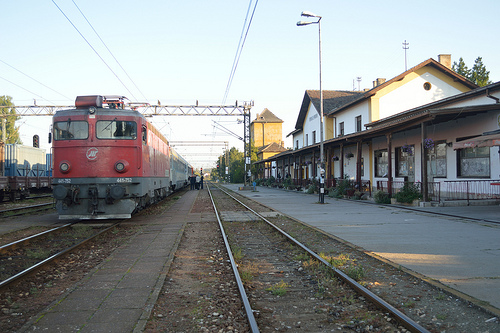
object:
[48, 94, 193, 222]
train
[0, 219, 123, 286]
tracks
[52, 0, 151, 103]
power lines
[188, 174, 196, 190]
people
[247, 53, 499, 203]
station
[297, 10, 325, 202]
light pole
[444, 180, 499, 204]
railing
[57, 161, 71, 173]
headlights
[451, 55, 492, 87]
trees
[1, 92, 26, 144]
tree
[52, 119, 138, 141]
windows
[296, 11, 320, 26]
lights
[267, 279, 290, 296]
grass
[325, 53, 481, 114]
roof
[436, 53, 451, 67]
chimney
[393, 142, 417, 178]
window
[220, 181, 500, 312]
pavement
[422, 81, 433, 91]
window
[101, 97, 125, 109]
antenna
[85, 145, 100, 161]
logo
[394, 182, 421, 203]
bush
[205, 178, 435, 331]
tracks